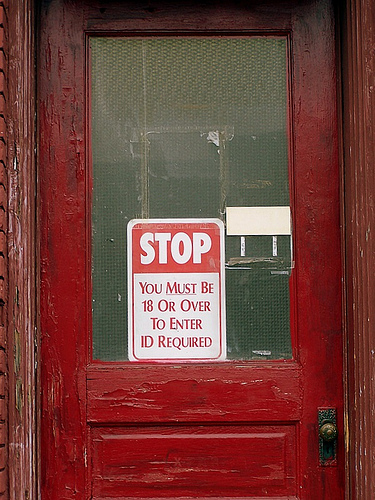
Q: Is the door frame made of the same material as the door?
A: Yes, both the door frame and the door are made of wood.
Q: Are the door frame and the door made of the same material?
A: Yes, both the door frame and the door are made of wood.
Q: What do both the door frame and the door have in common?
A: The material, both the door frame and the door are wooden.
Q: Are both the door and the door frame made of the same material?
A: Yes, both the door and the door frame are made of wood.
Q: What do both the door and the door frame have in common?
A: The material, both the door and the door frame are wooden.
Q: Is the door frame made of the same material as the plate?
A: No, the door frame is made of wood and the plate is made of metal.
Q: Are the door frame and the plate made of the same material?
A: No, the door frame is made of wood and the plate is made of metal.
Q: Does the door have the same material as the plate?
A: No, the door is made of wood and the plate is made of metal.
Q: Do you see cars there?
A: No, there are no cars.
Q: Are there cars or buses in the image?
A: No, there are no cars or buses.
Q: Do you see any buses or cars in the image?
A: No, there are no cars or buses.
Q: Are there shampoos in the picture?
A: No, there are no shampoos.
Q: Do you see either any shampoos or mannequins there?
A: No, there are no shampoos or mannequins.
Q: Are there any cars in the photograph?
A: No, there are no cars.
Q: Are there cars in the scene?
A: No, there are no cars.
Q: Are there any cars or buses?
A: No, there are no cars or buses.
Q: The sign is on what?
A: The sign is on the door.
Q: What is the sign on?
A: The sign is on the door.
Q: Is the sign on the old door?
A: Yes, the sign is on the door.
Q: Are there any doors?
A: Yes, there is a door.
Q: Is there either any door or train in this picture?
A: Yes, there is a door.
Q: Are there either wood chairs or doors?
A: Yes, there is a wood door.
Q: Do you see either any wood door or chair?
A: Yes, there is a wood door.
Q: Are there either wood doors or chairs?
A: Yes, there is a wood door.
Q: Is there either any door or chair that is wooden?
A: Yes, the door is wooden.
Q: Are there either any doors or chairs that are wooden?
A: Yes, the door is wooden.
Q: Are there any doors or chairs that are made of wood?
A: Yes, the door is made of wood.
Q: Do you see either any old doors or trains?
A: Yes, there is an old door.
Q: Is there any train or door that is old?
A: Yes, the door is old.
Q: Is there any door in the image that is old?
A: Yes, there is an old door.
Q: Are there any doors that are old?
A: Yes, there is an old door.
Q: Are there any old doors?
A: Yes, there is an old door.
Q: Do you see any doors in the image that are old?
A: Yes, there is a door that is old.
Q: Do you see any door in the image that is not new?
A: Yes, there is a old door.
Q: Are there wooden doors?
A: Yes, there is a wood door.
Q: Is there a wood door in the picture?
A: Yes, there is a wood door.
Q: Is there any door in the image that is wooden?
A: Yes, there is a door that is wooden.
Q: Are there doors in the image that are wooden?
A: Yes, there is a door that is wooden.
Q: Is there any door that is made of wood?
A: Yes, there is a door that is made of wood.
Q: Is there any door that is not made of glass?
A: Yes, there is a door that is made of wood.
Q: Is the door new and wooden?
A: No, the door is wooden but old.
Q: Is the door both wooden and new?
A: No, the door is wooden but old.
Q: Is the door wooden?
A: Yes, the door is wooden.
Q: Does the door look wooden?
A: Yes, the door is wooden.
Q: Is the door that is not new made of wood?
A: Yes, the door is made of wood.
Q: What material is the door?
A: The door is made of wood.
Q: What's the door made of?
A: The door is made of wood.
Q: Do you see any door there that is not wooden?
A: No, there is a door but it is wooden.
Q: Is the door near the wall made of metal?
A: No, the door is made of wood.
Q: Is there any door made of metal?
A: No, there is a door but it is made of wood.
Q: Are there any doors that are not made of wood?
A: No, there is a door but it is made of wood.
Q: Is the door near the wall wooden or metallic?
A: The door is wooden.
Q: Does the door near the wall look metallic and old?
A: No, the door is old but wooden.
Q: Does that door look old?
A: Yes, the door is old.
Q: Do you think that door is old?
A: Yes, the door is old.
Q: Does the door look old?
A: Yes, the door is old.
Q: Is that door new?
A: No, the door is old.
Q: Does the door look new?
A: No, the door is old.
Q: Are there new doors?
A: No, there is a door but it is old.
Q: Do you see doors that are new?
A: No, there is a door but it is old.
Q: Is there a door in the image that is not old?
A: No, there is a door but it is old.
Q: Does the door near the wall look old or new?
A: The door is old.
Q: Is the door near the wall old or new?
A: The door is old.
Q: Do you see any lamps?
A: No, there are no lamps.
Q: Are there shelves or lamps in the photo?
A: No, there are no lamps or shelves.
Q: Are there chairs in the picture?
A: No, there are no chairs.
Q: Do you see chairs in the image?
A: No, there are no chairs.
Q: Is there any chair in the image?
A: No, there are no chairs.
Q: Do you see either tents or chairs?
A: No, there are no chairs or tents.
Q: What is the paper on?
A: The paper is on the door.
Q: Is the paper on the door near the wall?
A: Yes, the paper is on the door.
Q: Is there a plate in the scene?
A: Yes, there is a plate.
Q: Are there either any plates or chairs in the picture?
A: Yes, there is a plate.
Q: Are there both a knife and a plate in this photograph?
A: No, there is a plate but no knives.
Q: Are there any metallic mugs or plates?
A: Yes, there is a metal plate.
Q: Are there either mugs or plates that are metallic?
A: Yes, the plate is metallic.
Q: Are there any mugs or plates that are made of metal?
A: Yes, the plate is made of metal.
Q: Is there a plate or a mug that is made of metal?
A: Yes, the plate is made of metal.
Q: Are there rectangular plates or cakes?
A: Yes, there is a rectangular plate.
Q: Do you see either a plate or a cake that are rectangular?
A: Yes, the plate is rectangular.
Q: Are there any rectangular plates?
A: Yes, there is a rectangular plate.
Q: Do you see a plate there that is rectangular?
A: Yes, there is a plate that is rectangular.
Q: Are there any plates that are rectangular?
A: Yes, there is a plate that is rectangular.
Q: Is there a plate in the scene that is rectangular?
A: Yes, there is a plate that is rectangular.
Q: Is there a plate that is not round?
A: Yes, there is a rectangular plate.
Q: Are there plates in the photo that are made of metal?
A: Yes, there is a plate that is made of metal.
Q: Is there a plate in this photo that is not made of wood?
A: Yes, there is a plate that is made of metal.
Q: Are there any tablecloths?
A: No, there are no tablecloths.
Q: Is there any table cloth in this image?
A: No, there are no tablecloths.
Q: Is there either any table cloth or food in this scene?
A: No, there are no tablecloths or food.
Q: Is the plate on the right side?
A: Yes, the plate is on the right of the image.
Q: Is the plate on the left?
A: No, the plate is on the right of the image.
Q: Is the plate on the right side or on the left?
A: The plate is on the right of the image.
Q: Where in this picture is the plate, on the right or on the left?
A: The plate is on the right of the image.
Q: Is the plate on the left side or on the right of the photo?
A: The plate is on the right of the image.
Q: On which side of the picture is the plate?
A: The plate is on the right of the image.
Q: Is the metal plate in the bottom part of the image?
A: Yes, the plate is in the bottom of the image.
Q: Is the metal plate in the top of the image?
A: No, the plate is in the bottom of the image.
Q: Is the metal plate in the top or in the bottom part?
A: The plate is in the bottom of the image.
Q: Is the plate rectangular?
A: Yes, the plate is rectangular.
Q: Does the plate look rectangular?
A: Yes, the plate is rectangular.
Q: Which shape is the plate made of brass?
A: The plate is rectangular.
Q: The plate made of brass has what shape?
A: The plate is rectangular.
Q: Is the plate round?
A: No, the plate is rectangular.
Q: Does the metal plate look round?
A: No, the plate is rectangular.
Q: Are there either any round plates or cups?
A: No, there is a plate but it is rectangular.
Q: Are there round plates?
A: No, there is a plate but it is rectangular.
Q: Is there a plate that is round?
A: No, there is a plate but it is rectangular.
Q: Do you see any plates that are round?
A: No, there is a plate but it is rectangular.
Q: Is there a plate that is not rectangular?
A: No, there is a plate but it is rectangular.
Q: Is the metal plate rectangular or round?
A: The plate is rectangular.